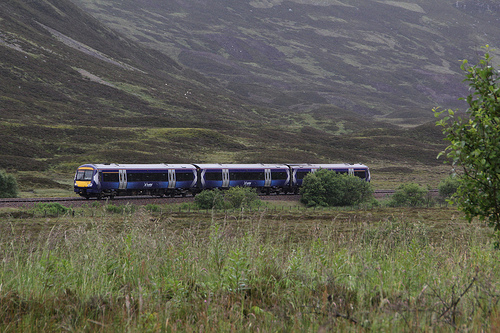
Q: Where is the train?
A: Countryside.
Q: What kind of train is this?
A: Passenger.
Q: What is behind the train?
A: Hill.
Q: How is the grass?
A: Tall.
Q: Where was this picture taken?
A: By a train track.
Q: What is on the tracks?
A: A train.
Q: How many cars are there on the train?
A: Three.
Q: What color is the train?
A: Blue and white.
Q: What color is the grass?
A: Green.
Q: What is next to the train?
A: Trees.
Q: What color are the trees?
A: Green.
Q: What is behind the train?
A: Hillside.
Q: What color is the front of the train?
A: Yellow.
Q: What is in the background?
A: Hillside.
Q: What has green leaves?
A: Tree.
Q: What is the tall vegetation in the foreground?
A: Grass.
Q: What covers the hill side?
A: Vegetation.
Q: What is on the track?
A: Train.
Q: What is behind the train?
A: A hill.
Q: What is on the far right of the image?
A: Tree.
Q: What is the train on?
A: Tracks.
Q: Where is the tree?
A: Far right.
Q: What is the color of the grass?
A: Green.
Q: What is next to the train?
A: Shrubs.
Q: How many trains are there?
A: 1.